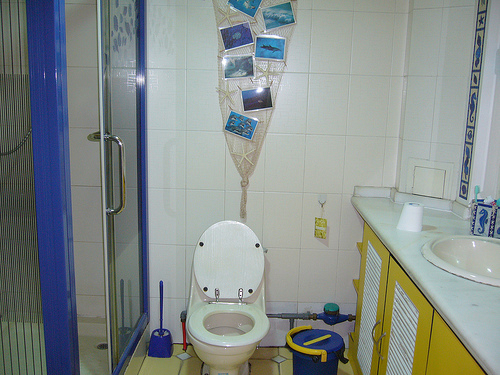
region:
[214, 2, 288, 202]
a bunch of pictures on the wall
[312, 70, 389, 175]
white tile in a bathroom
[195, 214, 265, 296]
the lid of the toilet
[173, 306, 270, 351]
the seat of the toilet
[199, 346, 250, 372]
the bowl of the toilet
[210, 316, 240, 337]
the water of a toilet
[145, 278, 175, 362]
a small blue toilet brush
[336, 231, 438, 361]
a set of yellow cabinets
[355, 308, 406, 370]
the silver handle of a cabinet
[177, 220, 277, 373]
this is a toilet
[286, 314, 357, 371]
this is a dust bin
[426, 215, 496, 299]
this is a sink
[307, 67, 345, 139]
this is a tile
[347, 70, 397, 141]
this is a tile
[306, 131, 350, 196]
this is a tile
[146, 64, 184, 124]
this is a tile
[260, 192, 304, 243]
this is a tile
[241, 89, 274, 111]
PICTURE ON THE WALL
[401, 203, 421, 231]
WHITE TISSUE ON THE COUNTER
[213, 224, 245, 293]
LID UP ON THE TOILET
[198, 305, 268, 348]
SEAT OF THE STOOL DOWN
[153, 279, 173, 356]
BLUE TOILET BRUSH IN THE CORNER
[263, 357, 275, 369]
TILE ON THE FLOOR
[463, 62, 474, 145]
BORDER AROUND THE EDGE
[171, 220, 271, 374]
white toilet bowl with the lid up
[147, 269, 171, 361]
a blue toilet brush in a holder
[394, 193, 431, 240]
a roll of toilet paper on a counter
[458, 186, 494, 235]
a toothbrush holder and toothbrush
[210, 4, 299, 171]
postcards hanging on a wall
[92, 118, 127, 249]
a metal handle on a shower door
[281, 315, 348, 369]
a blue and yellow garbage can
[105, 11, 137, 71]
decals on a shower door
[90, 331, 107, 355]
a shower water drain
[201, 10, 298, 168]
postcards attached to a net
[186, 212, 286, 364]
toilet in the bathroom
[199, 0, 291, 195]
pictures above the toilet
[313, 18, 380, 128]
tiles on the wall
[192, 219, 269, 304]
the lid of the toilet is up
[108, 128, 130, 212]
handle of the shower door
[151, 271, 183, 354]
the toilet brush beside the toilet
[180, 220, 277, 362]
the toilet is white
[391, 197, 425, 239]
toilet paper on the vanity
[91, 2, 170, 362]
shower door is open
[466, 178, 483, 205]
toothbrush in the cup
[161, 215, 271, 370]
toilet is white in color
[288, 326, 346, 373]
bucket is on the floor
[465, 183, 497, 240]
searhorse is on picture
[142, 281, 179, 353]
brush on the floor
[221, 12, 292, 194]
pictures on the wall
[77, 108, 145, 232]
handle on the door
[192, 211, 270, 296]
a white toilet lid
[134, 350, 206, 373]
tile on the floor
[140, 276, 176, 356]
a blue toilet cleaner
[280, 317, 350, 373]
bucket next to the toilet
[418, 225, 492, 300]
a white bathroom sink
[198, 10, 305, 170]
pictures on the wall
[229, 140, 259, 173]
star on the wall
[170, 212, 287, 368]
toilet with seat open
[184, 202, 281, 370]
toilet with seat open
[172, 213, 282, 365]
toilet with seat open